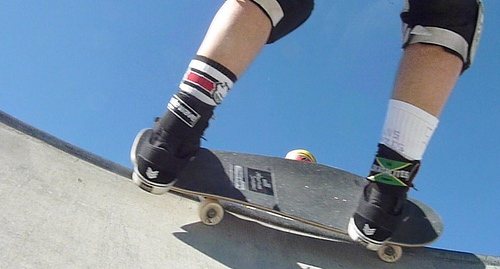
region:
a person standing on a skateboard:
[112, 43, 467, 266]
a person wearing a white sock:
[385, 91, 440, 154]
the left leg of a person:
[160, 0, 267, 142]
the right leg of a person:
[358, 10, 464, 185]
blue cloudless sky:
[67, 15, 158, 110]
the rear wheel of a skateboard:
[195, 202, 224, 227]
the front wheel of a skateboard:
[377, 244, 404, 262]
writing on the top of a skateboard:
[225, 159, 278, 198]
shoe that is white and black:
[120, 154, 188, 191]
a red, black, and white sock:
[176, 50, 236, 102]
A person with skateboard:
[122, 93, 474, 266]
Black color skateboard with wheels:
[200, 201, 413, 263]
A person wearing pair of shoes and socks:
[143, 92, 433, 253]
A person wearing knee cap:
[222, 0, 487, 47]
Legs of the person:
[215, 20, 456, 98]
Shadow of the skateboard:
[188, 221, 339, 267]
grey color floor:
[15, 155, 76, 250]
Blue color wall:
[37, 11, 129, 83]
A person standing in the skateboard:
[132, 115, 457, 245]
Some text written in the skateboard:
[226, 157, 284, 199]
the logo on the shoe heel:
[141, 160, 163, 182]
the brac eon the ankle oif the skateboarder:
[362, 138, 419, 221]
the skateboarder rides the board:
[134, 139, 449, 253]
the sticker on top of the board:
[227, 155, 287, 205]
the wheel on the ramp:
[195, 199, 227, 224]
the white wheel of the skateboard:
[378, 243, 403, 260]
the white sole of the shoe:
[127, 126, 146, 186]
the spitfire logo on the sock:
[209, 78, 232, 105]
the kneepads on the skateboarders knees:
[230, 0, 489, 73]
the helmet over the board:
[279, 146, 322, 167]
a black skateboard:
[125, 128, 454, 260]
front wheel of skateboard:
[371, 235, 405, 267]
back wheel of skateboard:
[193, 193, 229, 229]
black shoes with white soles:
[112, 122, 413, 252]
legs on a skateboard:
[112, 0, 484, 260]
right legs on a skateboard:
[348, 3, 480, 243]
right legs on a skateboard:
[126, 0, 303, 207]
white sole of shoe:
[119, 123, 185, 202]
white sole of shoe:
[341, 175, 409, 250]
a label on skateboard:
[221, 156, 282, 197]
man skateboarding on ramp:
[110, 85, 498, 260]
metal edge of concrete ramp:
[17, 96, 102, 181]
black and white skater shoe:
[108, 132, 196, 187]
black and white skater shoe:
[355, 188, 406, 263]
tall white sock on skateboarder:
[367, 74, 450, 144]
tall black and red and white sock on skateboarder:
[154, 60, 264, 156]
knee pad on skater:
[379, 23, 485, 92]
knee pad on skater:
[198, 12, 308, 34]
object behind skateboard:
[267, 128, 347, 178]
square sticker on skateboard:
[228, 160, 276, 194]